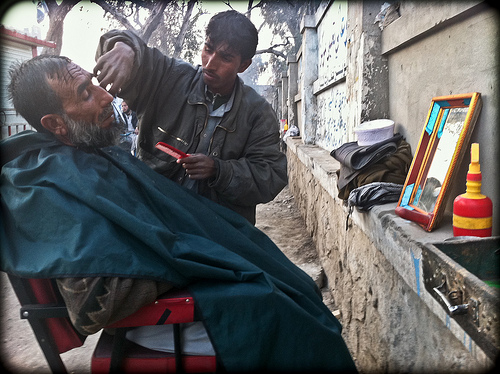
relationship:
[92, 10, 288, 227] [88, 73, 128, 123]
barber holding scissors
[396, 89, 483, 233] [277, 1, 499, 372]
mirror on wall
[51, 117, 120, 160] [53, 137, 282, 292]
neck covered by green cloth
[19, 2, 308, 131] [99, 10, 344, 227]
trees behind man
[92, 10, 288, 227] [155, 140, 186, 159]
barber holding comb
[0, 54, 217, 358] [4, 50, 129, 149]
man with gray hair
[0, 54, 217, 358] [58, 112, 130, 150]
man with beard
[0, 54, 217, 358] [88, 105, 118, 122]
man with mustache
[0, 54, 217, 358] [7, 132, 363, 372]
man wearing cape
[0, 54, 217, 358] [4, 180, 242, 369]
man sitting in chair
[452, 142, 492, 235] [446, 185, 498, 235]
bottle with stripes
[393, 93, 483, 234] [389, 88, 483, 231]
mirror with frame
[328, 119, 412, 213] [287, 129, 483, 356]
clothes on ledge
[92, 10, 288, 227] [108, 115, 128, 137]
barber cutting hair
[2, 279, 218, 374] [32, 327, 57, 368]
barber chair has metal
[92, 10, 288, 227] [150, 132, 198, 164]
barber holding comb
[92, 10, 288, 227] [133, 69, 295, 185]
barber wearing gray jacket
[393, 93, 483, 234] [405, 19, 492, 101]
mirror leaning against wall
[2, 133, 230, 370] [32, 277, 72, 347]
barber chair has cushion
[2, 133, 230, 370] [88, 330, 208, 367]
barber chair has cushion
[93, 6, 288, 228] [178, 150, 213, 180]
barber has hand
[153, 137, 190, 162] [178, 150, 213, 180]
red comb in hand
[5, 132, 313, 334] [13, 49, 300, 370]
blanket covering man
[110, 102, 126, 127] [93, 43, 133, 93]
silver scissors in hand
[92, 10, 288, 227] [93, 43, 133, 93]
barber has hand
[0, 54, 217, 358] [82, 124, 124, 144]
man has beard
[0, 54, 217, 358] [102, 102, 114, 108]
man has mustache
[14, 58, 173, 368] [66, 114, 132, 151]
man has hair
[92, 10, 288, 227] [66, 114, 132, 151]
barber cutting hair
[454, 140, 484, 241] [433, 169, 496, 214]
bottle has yellow stripes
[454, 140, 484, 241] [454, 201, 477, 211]
bottle has stripes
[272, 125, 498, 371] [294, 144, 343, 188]
wall has ledge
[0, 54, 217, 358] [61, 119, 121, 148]
man getting trimmed beard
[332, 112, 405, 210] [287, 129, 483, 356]
clothes on ledge